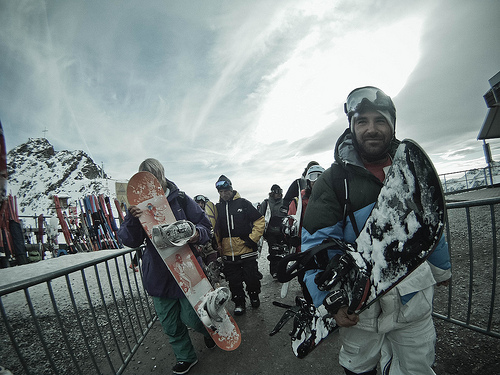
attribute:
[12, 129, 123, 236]
mountains — snow covered, snowy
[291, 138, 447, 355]
snowboard — black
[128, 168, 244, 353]
snowboard — orange, yellow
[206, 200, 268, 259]
jacket — yellow, black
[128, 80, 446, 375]
people — carrying snowboards, walking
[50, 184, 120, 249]
skis — leaning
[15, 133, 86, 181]
mountain tops — in view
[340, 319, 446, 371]
pants — white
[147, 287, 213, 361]
pants — green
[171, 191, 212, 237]
jacket — purple